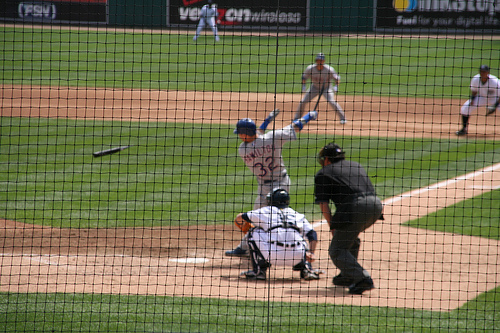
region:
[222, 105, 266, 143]
head of a person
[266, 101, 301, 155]
arm of a person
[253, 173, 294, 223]
head of a person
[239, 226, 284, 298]
leg of a person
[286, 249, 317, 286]
leg of a person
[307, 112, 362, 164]
head of a person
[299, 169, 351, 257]
leg of a person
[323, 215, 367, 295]
leg of a person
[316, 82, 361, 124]
leg of a person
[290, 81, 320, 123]
leg of a person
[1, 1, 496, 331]
black metal fence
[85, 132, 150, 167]
baseball bat in grass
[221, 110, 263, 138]
blue baseball hat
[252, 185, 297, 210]
black helmet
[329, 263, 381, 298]
pair of black shoes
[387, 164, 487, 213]
white line on baseball field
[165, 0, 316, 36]
sponser banner on side of baseball field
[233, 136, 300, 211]
grey and blue baseball uniform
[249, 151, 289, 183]
number on back of baseball jersey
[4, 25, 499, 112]
grass portion of baseball field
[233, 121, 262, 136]
player has blue helmet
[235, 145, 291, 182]
black and grey shirt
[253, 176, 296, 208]
player has grey pants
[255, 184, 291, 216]
catcher has black mask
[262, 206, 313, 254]
catcher has white shirt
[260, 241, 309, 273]
catcher has white pants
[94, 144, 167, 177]
batter breaks black bat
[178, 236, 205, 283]
home plate is white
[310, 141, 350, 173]
umpire has black mask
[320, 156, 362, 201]
umpire has black shirt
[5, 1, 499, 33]
advertisement billboards on the wall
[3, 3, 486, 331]
a black fence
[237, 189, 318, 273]
a baseball catcher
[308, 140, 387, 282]
an umpire behind the catcher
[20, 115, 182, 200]
grass on the baseball field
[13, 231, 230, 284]
the dirt on the baseball field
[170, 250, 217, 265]
the home base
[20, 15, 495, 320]
the baseball field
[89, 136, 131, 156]
the bat on the gas